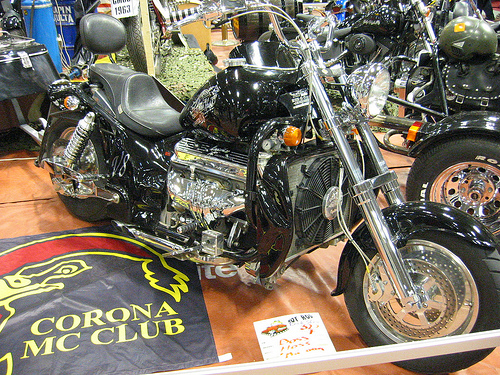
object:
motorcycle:
[34, 2, 499, 374]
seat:
[87, 62, 188, 140]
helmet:
[438, 15, 498, 63]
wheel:
[344, 230, 500, 374]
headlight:
[345, 62, 392, 114]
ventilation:
[295, 153, 351, 247]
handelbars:
[205, 0, 279, 26]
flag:
[0, 221, 220, 372]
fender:
[330, 199, 497, 299]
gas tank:
[177, 62, 307, 146]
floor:
[2, 339, 498, 374]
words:
[28, 300, 185, 338]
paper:
[251, 310, 338, 363]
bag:
[1, 43, 59, 100]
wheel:
[47, 120, 122, 222]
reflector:
[282, 125, 301, 147]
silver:
[204, 188, 215, 201]